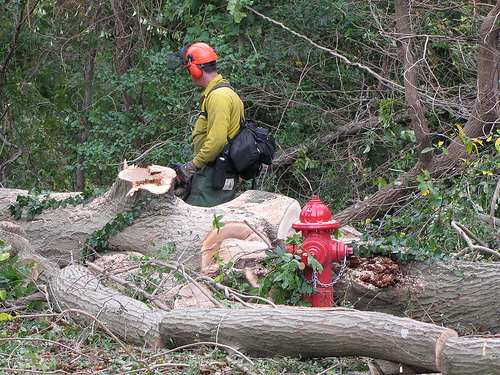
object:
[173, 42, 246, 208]
man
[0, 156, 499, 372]
tree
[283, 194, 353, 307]
fire hydrant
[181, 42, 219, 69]
helmet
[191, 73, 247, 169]
jacket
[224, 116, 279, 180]
backpack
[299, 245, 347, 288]
chain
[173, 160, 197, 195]
glove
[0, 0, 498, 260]
brush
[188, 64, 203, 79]
ear muffs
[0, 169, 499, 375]
ground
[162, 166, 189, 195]
saw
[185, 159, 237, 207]
pant